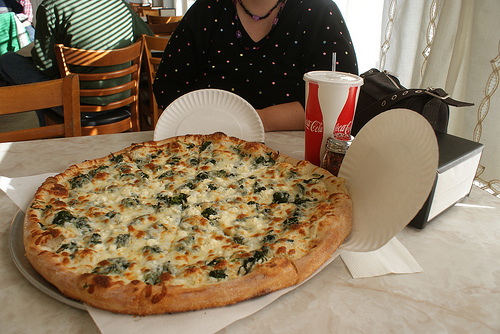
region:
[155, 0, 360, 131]
Lady sitting at table that has pizza on it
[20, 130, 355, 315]
Mostly cheese pizza sitting on a table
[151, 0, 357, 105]
Polka dotted black shirt on a lady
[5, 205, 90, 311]
Small part of silver pizza pan under a pizza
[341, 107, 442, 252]
White paper plate partly under a pizza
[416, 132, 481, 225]
Black napkin holder on table with pizza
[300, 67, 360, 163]
Red and white paper coca cola cup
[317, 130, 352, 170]
Spice shaker on table next to a pizza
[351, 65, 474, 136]
Black purse on a table next to a lady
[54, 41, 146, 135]
Brown, wooden chair at a restaurant serving pizza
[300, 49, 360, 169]
Coca Cola paper cup with lid and straw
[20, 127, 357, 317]
Whole spinach and cheese traditional crust pizza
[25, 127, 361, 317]
Whole pizza with cheese and spinach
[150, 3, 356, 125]
Plus sized black blouse with multi-colored polka dots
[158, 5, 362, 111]
Black milti-colored polka dotted blouse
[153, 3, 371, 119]
Black blouse with brightly colored and multi0colored polka dots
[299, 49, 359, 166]
Disposable Coca Cola cup with lid and straw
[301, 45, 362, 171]
Disposable Coke fountain drinking cup with lid and straw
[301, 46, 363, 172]
Disposable cola fountain drinking cup with lid and straw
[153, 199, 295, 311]
Slice of spinach and cheese pizza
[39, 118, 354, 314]
pizza on the table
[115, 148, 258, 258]
toppings on the pizza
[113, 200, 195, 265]
cheese on the pizza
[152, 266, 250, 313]
crust of the pizza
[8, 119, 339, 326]
round pizza on the table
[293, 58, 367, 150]
cup next to pizza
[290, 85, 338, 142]
red object on the cup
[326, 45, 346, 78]
straw in the cup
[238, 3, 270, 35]
necklace around lady's neck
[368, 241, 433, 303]
napkin on the table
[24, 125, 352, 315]
a large pizza on a table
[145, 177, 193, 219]
the topping on a pizza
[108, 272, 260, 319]
the crust of a pizza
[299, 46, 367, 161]
a cup with a lid and straw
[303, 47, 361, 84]
a straw in a lid on a cup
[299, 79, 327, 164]
a red Coca Cola bottle on the side of a cup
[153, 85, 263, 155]
a paper plate by a pizza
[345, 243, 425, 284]
a white napkin on a table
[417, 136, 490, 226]
a napkin holder on a table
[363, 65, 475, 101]
the zipper of a hand bag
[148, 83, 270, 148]
White paper plate ready for pizza.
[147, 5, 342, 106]
Woman wearing a shirt with dots.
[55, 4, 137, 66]
Window stripes on the man.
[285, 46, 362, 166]
Coke in a cup.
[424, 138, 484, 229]
Napkin dispenser on the table.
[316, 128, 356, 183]
Red pepper flakes in a jar.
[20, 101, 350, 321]
Large pizza ready to be eaten.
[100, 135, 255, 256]
Spinach and cheese on the pizza.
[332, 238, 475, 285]
Napkin under the paper plate.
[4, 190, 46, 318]
Silver pan under the pizza.